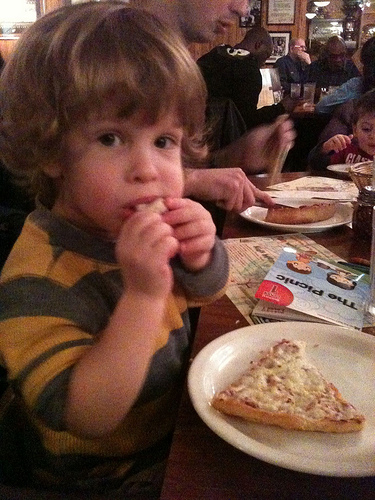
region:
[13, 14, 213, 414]
young kid eating food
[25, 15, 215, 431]
young kid with food in his mouth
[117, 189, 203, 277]
hands bringing food to mouth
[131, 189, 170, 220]
small piece of food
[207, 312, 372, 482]
cheese pizza on a plate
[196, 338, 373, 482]
white paper plate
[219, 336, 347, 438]
small slice of pizza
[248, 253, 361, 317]
kids book on table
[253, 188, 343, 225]
plate filled with pizza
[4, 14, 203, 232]
head of young kid looking forward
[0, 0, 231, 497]
Little bond boy with food in his mouth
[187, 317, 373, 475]
White plate with a slice of pizza on it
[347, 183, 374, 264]
Small glass bottle with metal top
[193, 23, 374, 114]
Group of people eating and drinking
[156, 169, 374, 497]
Rectangular wooden table with food on it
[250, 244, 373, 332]
Book with colorful cartoons on the cover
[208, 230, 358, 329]
Restaurant menu on the table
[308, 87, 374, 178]
Little boy eating out of a white plate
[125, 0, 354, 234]
Man eating pizza with silver utensils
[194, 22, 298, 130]
Man in a black shirt reading menu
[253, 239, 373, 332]
Children's coloring book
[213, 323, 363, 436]
A dinner plate of pizza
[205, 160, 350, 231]
Person cutting pizza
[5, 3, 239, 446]
Young child eating pizza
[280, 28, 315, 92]
Gentleman cleaning his face with napkin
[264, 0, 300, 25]
Decorative picture on wall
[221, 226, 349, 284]
Restaurant menu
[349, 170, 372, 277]
Metal and glass shaker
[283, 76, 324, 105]
Standing table desert menus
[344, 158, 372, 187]
Bread stick basket or appetizers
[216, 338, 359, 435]
cheese pizza on plate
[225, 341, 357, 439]
slice of cheese pizza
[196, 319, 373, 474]
white ceramic plate on table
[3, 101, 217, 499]
child eating cheese pizza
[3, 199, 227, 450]
grey and yellow shirt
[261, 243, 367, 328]
childs book on table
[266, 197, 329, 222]
pizza slice on plate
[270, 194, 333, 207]
white plastic dinner knife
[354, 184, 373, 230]
glass and metal pepper shaker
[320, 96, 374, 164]
child sitting at table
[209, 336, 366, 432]
slice of pizza on plate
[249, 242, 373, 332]
book on the table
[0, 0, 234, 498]
child wearing stripe sweater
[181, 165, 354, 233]
right hand holding a knife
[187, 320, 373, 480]
round and white plate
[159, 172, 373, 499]
wooden and brown table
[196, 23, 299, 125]
man wearing dark shirt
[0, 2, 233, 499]
child biting food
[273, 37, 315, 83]
man wearing glasses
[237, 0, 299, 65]
three pictures frames on wall